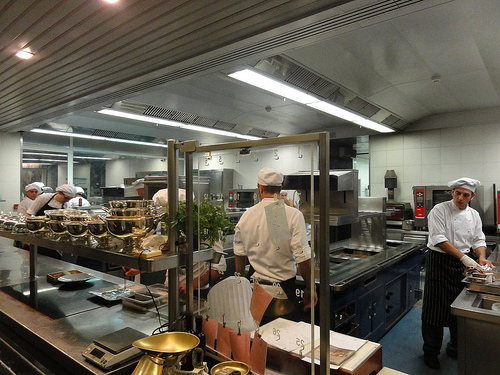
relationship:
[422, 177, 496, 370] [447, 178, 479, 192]
cook has hat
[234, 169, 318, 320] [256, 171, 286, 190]
cook has hat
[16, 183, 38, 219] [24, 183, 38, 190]
cook has hat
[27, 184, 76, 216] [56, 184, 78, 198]
cook has hat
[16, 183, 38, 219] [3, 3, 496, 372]
cook in kitchen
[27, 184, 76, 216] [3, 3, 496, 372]
cook in kitchen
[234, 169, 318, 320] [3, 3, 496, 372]
cook in kitchen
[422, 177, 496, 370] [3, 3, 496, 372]
cook in kitchen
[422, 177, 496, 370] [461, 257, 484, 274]
cook wearing glove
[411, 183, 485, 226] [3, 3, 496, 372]
microwave in kitchen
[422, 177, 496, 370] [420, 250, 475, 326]
cook wearing apron